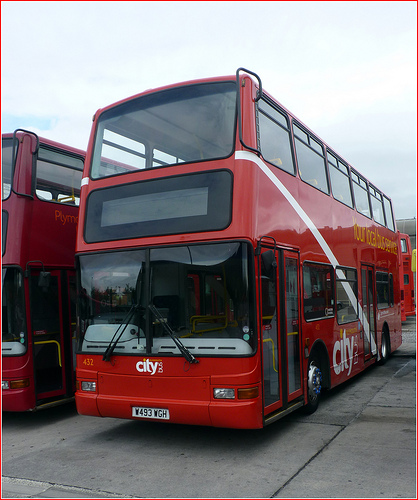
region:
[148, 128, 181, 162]
part of a window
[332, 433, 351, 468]
aprt of a floor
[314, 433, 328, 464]
part of a floor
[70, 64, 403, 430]
red double decker bus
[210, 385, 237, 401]
white headlight on the bus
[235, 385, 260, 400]
orange turn signal on the bus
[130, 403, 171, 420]
white and black license plate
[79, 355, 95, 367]
yellow numbers on the bus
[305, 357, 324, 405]
silver rims on the bus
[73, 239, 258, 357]
clear windshield on the bus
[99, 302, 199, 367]
black wipers on the bus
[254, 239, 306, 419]
double doors on the bus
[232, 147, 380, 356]
white line on the side of the bus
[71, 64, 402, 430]
a red double decked bus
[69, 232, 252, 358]
the windshield of a bus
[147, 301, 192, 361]
the windshield wipers of bus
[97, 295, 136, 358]
the windshield wipers of bus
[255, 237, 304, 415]
the doors of a bus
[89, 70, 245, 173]
the window on the top floor of a double decked bus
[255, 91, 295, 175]
a window on a bus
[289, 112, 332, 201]
a window on a bus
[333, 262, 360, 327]
a window on a bus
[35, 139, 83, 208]
a window on a bus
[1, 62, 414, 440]
Two black and red double decker busses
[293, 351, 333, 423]
Black tire on b us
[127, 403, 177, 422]
Black and white license plate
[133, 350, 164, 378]
White logo on front of bus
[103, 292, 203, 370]
Black wiper blades on bus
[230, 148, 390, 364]
White stripe on bus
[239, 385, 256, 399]
Small orange reflector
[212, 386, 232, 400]
Small square headlight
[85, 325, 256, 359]
White dashboard in bus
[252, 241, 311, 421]
Two double doors on bus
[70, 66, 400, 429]
a red double decker bus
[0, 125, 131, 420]
part of a bus left of the double decker bus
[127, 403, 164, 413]
white license plate on the bus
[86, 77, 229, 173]
top windshield on the bus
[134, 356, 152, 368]
word in white on the front of the bus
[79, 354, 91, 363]
yellow numbers on left front of the bus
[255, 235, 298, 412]
first door on the side of the bus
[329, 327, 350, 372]
white word on side of the bus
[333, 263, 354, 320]
window on side of bus with white stripe on it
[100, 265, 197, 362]
windshield wipers on the bus